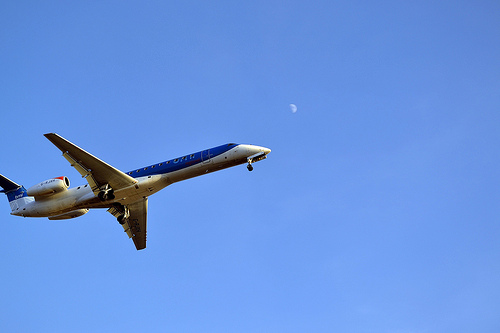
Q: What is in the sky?
A: A jet airplane.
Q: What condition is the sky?
A: Clear blue.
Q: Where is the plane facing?
A: To the right.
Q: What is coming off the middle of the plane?
A: Wings.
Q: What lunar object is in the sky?
A: The moon.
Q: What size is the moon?
A: Half circle.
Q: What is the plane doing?
A: Flying through the sky.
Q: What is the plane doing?
A: Taking off.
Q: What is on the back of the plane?
A: Tail and engines.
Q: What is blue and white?
A: Body of a jet plane.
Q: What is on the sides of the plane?
A: The wings.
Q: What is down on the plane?
A: The landing gear.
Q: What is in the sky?
A: A blue and white plane.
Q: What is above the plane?
A: Clear blue skies.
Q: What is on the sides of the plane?
A: The wings.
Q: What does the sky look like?
A: Clear and blue.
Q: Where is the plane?
A: In the air.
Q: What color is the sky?
A: Blue.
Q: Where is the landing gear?
A: In the down position.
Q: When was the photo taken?
A: Daytime.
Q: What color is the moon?
A: White.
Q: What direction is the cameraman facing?
A: Up.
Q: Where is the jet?
A: In the sky.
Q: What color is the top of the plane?
A: Blue.